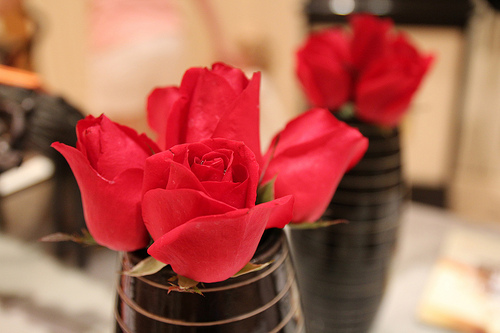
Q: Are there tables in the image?
A: Yes, there is a table.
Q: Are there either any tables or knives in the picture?
A: Yes, there is a table.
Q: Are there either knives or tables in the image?
A: Yes, there is a table.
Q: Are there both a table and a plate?
A: No, there is a table but no plates.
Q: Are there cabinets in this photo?
A: No, there are no cabinets.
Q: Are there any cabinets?
A: No, there are no cabinets.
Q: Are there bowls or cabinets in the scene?
A: No, there are no cabinets or bowls.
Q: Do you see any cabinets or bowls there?
A: No, there are no cabinets or bowls.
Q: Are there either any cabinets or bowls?
A: No, there are no cabinets or bowls.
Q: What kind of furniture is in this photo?
A: The furniture is a table.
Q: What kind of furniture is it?
A: The piece of furniture is a table.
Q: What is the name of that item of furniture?
A: This is a table.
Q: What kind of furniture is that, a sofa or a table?
A: This is a table.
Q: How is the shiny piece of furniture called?
A: The piece of furniture is a table.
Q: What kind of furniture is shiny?
A: The furniture is a table.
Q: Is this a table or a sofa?
A: This is a table.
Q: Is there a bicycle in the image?
A: No, there are no bicycles.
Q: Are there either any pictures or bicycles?
A: No, there are no bicycles or pictures.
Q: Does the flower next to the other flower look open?
A: No, the flower is closed.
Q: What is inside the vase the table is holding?
A: The flower is inside the vase.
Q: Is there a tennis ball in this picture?
A: No, there are no tennis balls.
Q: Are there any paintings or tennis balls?
A: No, there are no tennis balls or paintings.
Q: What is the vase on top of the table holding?
A: The vase is holding the flower.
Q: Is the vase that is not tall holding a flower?
A: Yes, the vase is holding a flower.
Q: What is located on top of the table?
A: The vase is on top of the table.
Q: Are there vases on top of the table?
A: Yes, there is a vase on top of the table.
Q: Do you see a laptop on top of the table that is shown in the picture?
A: No, there is a vase on top of the table.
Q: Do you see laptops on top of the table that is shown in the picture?
A: No, there is a vase on top of the table.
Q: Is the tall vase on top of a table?
A: Yes, the vase is on top of a table.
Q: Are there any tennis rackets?
A: No, there are no tennis rackets.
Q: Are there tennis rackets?
A: No, there are no tennis rackets.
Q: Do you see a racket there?
A: No, there are no rackets.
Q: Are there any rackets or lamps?
A: No, there are no rackets or lamps.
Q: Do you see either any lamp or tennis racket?
A: No, there are no rackets or lamps.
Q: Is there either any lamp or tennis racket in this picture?
A: No, there are no rackets or lamps.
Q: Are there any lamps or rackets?
A: No, there are no rackets or lamps.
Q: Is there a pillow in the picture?
A: No, there are no pillows.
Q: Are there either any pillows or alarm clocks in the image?
A: No, there are no pillows or alarm clocks.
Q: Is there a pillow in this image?
A: No, there are no pillows.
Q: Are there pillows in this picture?
A: No, there are no pillows.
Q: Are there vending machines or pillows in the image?
A: No, there are no pillows or vending machines.